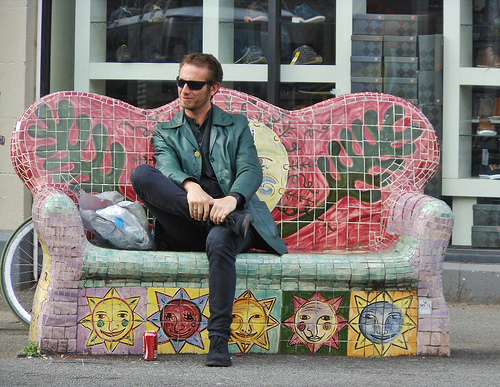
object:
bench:
[9, 86, 454, 355]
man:
[130, 53, 287, 366]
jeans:
[130, 164, 255, 340]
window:
[105, 0, 335, 111]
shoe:
[206, 337, 232, 367]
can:
[142, 331, 158, 360]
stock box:
[473, 204, 500, 226]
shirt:
[183, 105, 225, 198]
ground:
[0, 301, 500, 386]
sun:
[78, 287, 146, 353]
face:
[93, 297, 134, 342]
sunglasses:
[176, 76, 210, 90]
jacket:
[152, 104, 288, 256]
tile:
[345, 102, 364, 125]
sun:
[348, 291, 417, 357]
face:
[359, 301, 404, 345]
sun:
[147, 287, 211, 354]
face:
[160, 299, 201, 339]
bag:
[78, 191, 156, 250]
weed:
[22, 340, 39, 356]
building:
[0, 0, 500, 264]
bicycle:
[0, 217, 44, 328]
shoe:
[116, 44, 131, 62]